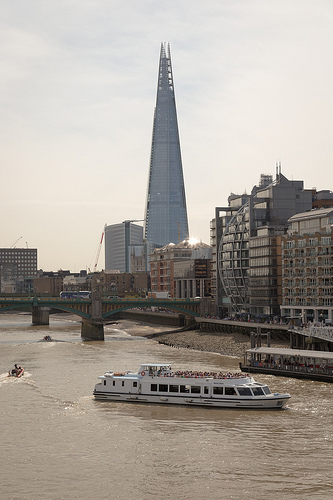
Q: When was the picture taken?
A: Day time.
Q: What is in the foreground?
A: A body of water.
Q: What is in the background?
A: The sky.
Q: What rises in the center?
A: A tall building.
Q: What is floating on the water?
A: Boats.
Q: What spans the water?
A: A bridge.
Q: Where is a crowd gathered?
A: On the top deck of the cruise ship.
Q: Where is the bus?
A: On the bridge.